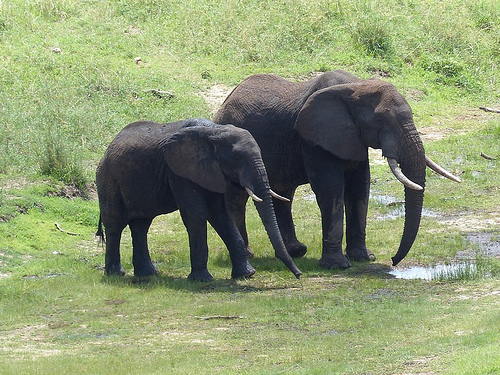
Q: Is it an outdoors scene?
A: Yes, it is outdoors.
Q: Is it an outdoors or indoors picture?
A: It is outdoors.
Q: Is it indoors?
A: No, it is outdoors.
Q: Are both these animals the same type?
A: Yes, all the animals are elephants.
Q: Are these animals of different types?
A: No, all the animals are elephants.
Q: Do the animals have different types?
A: No, all the animals are elephants.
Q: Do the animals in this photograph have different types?
A: No, all the animals are elephants.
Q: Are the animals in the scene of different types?
A: No, all the animals are elephants.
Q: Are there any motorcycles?
A: No, there are no motorcycles.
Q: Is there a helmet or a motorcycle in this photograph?
A: No, there are no motorcycles or helmets.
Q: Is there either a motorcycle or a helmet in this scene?
A: No, there are no motorcycles or helmets.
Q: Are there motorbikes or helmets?
A: No, there are no motorbikes or helmets.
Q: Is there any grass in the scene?
A: Yes, there is grass.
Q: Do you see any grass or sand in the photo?
A: Yes, there is grass.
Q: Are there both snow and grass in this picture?
A: No, there is grass but no snow.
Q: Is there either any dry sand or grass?
A: Yes, there is dry grass.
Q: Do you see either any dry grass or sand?
A: Yes, there is dry grass.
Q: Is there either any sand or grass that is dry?
A: Yes, the grass is dry.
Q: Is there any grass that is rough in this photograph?
A: Yes, there is rough grass.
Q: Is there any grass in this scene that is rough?
A: Yes, there is grass that is rough.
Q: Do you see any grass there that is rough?
A: Yes, there is grass that is rough.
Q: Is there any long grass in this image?
A: Yes, there is long grass.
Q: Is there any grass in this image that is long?
A: Yes, there is grass that is long.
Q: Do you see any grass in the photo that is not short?
A: Yes, there is long grass.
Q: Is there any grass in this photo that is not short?
A: Yes, there is long grass.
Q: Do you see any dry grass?
A: Yes, there is dry grass.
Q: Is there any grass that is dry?
A: Yes, there is grass that is dry.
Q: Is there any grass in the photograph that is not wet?
A: Yes, there is dry grass.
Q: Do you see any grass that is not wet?
A: Yes, there is dry grass.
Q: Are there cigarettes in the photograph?
A: No, there are no cigarettes.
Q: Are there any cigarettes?
A: No, there are no cigarettes.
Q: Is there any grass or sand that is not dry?
A: No, there is grass but it is dry.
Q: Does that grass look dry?
A: Yes, the grass is dry.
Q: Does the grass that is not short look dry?
A: Yes, the grass is dry.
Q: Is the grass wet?
A: No, the grass is dry.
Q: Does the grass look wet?
A: No, the grass is dry.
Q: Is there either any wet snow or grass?
A: No, there is grass but it is dry.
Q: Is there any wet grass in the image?
A: No, there is grass but it is dry.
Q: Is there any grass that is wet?
A: No, there is grass but it is dry.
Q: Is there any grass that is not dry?
A: No, there is grass but it is dry.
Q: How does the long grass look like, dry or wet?
A: The grass is dry.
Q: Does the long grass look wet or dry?
A: The grass is dry.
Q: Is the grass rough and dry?
A: Yes, the grass is rough and dry.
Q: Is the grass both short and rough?
A: No, the grass is rough but long.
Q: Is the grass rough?
A: Yes, the grass is rough.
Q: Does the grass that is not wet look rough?
A: Yes, the grass is rough.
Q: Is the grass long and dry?
A: Yes, the grass is long and dry.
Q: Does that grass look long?
A: Yes, the grass is long.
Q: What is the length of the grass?
A: The grass is long.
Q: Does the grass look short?
A: No, the grass is long.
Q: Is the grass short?
A: No, the grass is long.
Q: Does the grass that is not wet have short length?
A: No, the grass is long.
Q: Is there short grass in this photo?
A: No, there is grass but it is long.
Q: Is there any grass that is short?
A: No, there is grass but it is long.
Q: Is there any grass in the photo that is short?
A: No, there is grass but it is long.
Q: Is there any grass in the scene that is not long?
A: No, there is grass but it is long.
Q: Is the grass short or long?
A: The grass is long.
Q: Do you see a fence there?
A: No, there are no fences.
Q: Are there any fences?
A: No, there are no fences.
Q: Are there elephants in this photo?
A: Yes, there is an elephant.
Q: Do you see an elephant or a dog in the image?
A: Yes, there is an elephant.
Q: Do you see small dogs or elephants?
A: Yes, there is a small elephant.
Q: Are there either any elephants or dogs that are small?
A: Yes, the elephant is small.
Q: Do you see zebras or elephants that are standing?
A: Yes, the elephant is standing.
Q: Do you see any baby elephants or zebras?
A: Yes, there is a baby elephant.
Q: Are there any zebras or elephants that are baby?
A: Yes, the elephant is a baby.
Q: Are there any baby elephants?
A: Yes, there is a baby elephant.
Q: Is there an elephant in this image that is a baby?
A: Yes, there is an elephant that is a baby.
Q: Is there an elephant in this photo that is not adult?
A: Yes, there is an baby elephant.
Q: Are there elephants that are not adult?
A: Yes, there is an baby elephant.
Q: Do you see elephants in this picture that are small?
A: Yes, there is a small elephant.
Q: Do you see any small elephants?
A: Yes, there is a small elephant.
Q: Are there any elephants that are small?
A: Yes, there is an elephant that is small.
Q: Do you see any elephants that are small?
A: Yes, there is an elephant that is small.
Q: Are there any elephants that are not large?
A: Yes, there is a small elephant.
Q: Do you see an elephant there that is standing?
A: Yes, there is an elephant that is standing.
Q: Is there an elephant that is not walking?
A: Yes, there is an elephant that is standing.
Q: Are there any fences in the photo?
A: No, there are no fences.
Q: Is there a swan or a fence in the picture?
A: No, there are no fences or swans.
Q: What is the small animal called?
A: The animal is an elephant.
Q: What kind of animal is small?
A: The animal is an elephant.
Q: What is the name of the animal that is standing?
A: The animal is an elephant.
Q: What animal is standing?
A: The animal is an elephant.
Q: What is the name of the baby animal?
A: The animal is an elephant.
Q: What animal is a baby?
A: The animal is an elephant.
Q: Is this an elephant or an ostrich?
A: This is an elephant.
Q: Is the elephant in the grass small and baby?
A: Yes, the elephant is small and baby.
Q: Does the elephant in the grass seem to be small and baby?
A: Yes, the elephant is small and baby.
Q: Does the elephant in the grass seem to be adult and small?
A: No, the elephant is small but baby.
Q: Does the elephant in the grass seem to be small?
A: Yes, the elephant is small.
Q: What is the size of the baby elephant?
A: The elephant is small.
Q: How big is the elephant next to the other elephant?
A: The elephant is small.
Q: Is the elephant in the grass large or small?
A: The elephant is small.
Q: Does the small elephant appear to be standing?
A: Yes, the elephant is standing.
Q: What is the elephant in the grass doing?
A: The elephant is standing.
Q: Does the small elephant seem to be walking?
A: No, the elephant is standing.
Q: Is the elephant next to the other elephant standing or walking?
A: The elephant is standing.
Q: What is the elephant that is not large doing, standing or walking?
A: The elephant is standing.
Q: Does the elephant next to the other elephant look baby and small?
A: Yes, the elephant is a baby and small.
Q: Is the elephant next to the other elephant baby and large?
A: No, the elephant is a baby but small.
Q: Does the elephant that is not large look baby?
A: Yes, the elephant is a baby.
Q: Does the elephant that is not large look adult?
A: No, the elephant is a baby.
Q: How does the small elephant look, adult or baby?
A: The elephant is a baby.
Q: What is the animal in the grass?
A: The animal is an elephant.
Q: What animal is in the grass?
A: The animal is an elephant.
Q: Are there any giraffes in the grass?
A: No, there is an elephant in the grass.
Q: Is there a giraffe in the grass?
A: No, there is an elephant in the grass.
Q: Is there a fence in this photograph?
A: No, there are no fences.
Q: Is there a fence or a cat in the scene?
A: No, there are no fences or cats.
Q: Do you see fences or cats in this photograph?
A: No, there are no fences or cats.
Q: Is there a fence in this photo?
A: No, there are no fences.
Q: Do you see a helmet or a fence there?
A: No, there are no fences or helmets.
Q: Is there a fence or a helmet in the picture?
A: No, there are no fences or helmets.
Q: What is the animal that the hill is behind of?
A: The animal is an elephant.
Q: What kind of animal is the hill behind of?
A: The hill is behind the elephant.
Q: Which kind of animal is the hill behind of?
A: The hill is behind the elephant.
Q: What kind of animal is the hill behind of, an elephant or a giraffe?
A: The hill is behind an elephant.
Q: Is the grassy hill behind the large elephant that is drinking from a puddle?
A: Yes, the hill is behind the elephant.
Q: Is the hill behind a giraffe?
A: No, the hill is behind the elephant.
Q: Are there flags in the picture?
A: No, there are no flags.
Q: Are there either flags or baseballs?
A: No, there are no flags or baseballs.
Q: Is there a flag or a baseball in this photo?
A: No, there are no flags or baseballs.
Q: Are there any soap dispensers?
A: No, there are no soap dispensers.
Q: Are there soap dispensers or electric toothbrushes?
A: No, there are no soap dispensers or electric toothbrushes.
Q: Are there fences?
A: No, there are no fences.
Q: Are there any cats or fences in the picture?
A: No, there are no fences or cats.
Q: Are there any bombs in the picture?
A: No, there are no bombs.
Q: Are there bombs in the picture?
A: No, there are no bombs.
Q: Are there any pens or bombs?
A: No, there are no bombs or pens.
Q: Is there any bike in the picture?
A: No, there are no bikes.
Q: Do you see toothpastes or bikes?
A: No, there are no bikes or toothpastes.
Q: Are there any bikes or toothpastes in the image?
A: No, there are no bikes or toothpastes.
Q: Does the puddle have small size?
A: Yes, the puddle is small.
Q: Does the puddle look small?
A: Yes, the puddle is small.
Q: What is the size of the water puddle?
A: The puddle is small.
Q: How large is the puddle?
A: The puddle is small.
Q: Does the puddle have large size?
A: No, the puddle is small.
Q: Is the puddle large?
A: No, the puddle is small.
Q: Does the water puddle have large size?
A: No, the puddle is small.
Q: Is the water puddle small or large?
A: The puddle is small.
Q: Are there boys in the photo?
A: No, there are no boys.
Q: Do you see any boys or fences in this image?
A: No, there are no boys or fences.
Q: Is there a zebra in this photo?
A: No, there are no zebras.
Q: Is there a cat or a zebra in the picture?
A: No, there are no zebras or cats.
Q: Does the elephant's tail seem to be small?
A: Yes, the tail is small.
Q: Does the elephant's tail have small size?
A: Yes, the tail is small.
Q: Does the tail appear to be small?
A: Yes, the tail is small.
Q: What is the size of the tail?
A: The tail is small.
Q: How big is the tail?
A: The tail is small.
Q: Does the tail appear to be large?
A: No, the tail is small.